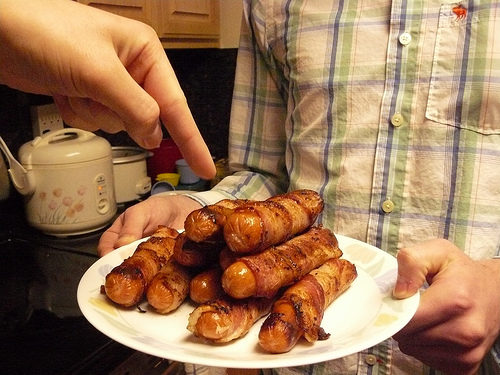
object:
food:
[102, 224, 182, 311]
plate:
[75, 225, 422, 370]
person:
[96, 0, 500, 371]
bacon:
[235, 194, 315, 254]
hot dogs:
[144, 252, 192, 315]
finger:
[125, 54, 217, 182]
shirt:
[176, 0, 500, 375]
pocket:
[422, 0, 500, 137]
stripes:
[296, 64, 381, 95]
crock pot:
[0, 127, 120, 241]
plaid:
[285, 24, 335, 74]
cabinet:
[71, 0, 222, 52]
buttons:
[390, 113, 405, 127]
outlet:
[30, 102, 64, 139]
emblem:
[450, 0, 472, 25]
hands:
[390, 237, 500, 375]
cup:
[154, 172, 181, 187]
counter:
[0, 304, 136, 375]